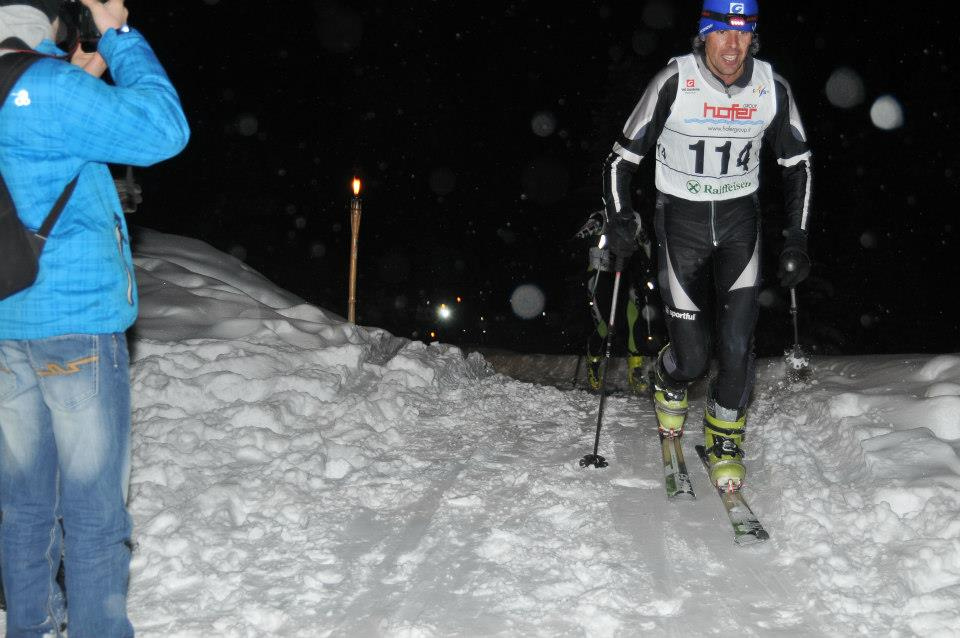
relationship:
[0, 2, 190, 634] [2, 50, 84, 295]
person carrying backpack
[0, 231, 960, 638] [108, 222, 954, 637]
snow in snow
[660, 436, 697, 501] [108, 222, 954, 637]
ski in snow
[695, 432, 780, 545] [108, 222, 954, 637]
ski in snow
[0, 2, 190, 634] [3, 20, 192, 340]
person wearing jacket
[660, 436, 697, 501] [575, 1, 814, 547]
ski on man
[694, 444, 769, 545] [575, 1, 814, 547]
ski on man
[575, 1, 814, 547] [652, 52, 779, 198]
man wearing jersey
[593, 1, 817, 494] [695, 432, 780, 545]
man standing on ski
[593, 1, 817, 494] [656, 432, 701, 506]
man standing on ski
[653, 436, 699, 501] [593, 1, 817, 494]
ski on man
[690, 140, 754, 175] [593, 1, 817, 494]
number on man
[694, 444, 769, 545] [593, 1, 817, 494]
ski on man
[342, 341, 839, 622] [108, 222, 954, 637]
track in snow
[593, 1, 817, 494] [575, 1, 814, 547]
man wearing man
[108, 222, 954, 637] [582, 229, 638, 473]
snow on pole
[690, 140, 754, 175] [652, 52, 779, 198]
number on jersey